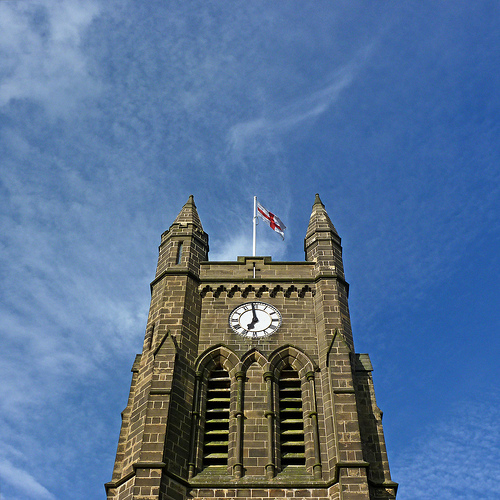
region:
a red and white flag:
[242, 170, 289, 260]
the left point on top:
[305, 178, 347, 215]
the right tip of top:
[145, 183, 227, 223]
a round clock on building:
[227, 300, 291, 340]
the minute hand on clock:
[249, 303, 256, 323]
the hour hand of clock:
[245, 311, 256, 334]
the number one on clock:
[261, 302, 269, 316]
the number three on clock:
[270, 313, 282, 323]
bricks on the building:
[138, 409, 168, 444]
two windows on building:
[193, 344, 329, 479]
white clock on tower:
[110, 282, 367, 496]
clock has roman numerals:
[217, 290, 294, 357]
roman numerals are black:
[221, 296, 293, 353]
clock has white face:
[222, 296, 288, 351]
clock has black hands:
[215, 272, 287, 348]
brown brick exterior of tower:
[247, 289, 337, 368]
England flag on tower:
[242, 187, 282, 253]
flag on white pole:
[240, 207, 270, 262]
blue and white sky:
[18, 41, 86, 194]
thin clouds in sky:
[39, 67, 153, 309]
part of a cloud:
[263, 48, 308, 130]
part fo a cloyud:
[46, 371, 61, 411]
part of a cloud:
[22, 338, 61, 398]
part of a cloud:
[384, 335, 428, 407]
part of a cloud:
[45, 316, 80, 399]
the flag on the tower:
[242, 189, 289, 252]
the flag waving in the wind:
[254, 202, 286, 241]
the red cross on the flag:
[257, 204, 284, 235]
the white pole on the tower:
[250, 192, 261, 266]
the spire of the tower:
[169, 188, 208, 229]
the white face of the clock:
[230, 295, 285, 338]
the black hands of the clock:
[240, 297, 260, 334]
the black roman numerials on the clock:
[230, 300, 276, 335]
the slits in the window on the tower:
[273, 369, 309, 473]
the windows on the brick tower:
[197, 344, 314, 481]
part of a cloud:
[435, 450, 459, 481]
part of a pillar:
[263, 423, 276, 481]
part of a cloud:
[379, 296, 400, 347]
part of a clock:
[241, 310, 262, 343]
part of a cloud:
[38, 376, 79, 430]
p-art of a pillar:
[301, 413, 323, 464]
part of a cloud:
[50, 370, 67, 401]